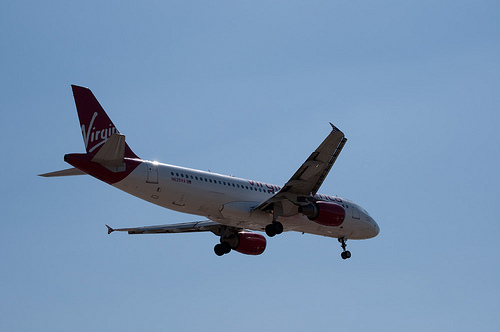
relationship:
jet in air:
[40, 85, 378, 260] [1, 2, 499, 330]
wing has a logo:
[255, 121, 347, 212] [80, 111, 119, 154]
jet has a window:
[35, 84, 382, 261] [229, 183, 235, 189]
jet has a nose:
[35, 84, 382, 261] [367, 214, 379, 239]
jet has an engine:
[35, 84, 382, 261] [299, 202, 346, 227]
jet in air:
[35, 84, 382, 261] [1, 2, 499, 331]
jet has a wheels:
[35, 84, 382, 261] [264, 220, 284, 237]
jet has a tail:
[35, 84, 382, 261] [65, 153, 91, 171]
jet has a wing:
[35, 84, 382, 261] [255, 121, 347, 212]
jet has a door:
[35, 84, 382, 261] [146, 164, 158, 183]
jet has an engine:
[40, 85, 378, 260] [299, 202, 346, 227]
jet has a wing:
[40, 85, 378, 260] [255, 121, 347, 212]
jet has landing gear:
[40, 85, 378, 260] [266, 206, 283, 238]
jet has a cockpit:
[35, 84, 382, 261] [358, 204, 371, 217]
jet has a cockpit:
[40, 85, 378, 260] [358, 204, 371, 217]